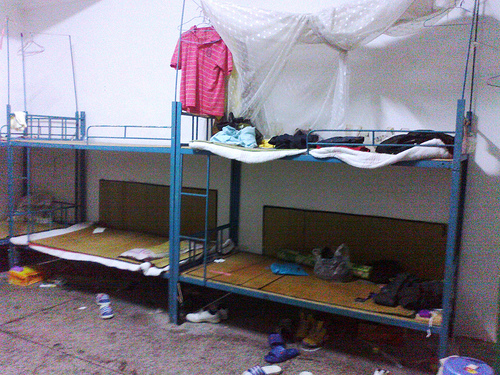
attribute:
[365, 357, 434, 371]
scene — outdoors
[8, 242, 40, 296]
box — orange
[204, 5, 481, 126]
sheet — white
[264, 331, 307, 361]
sandals — blue